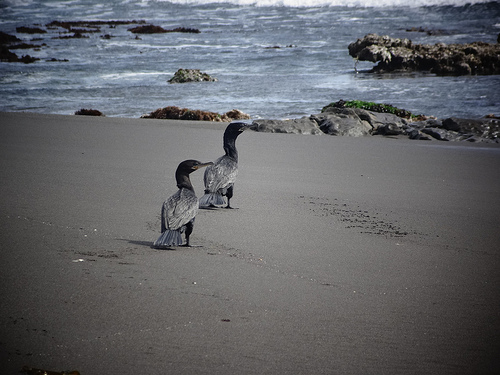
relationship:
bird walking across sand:
[150, 158, 217, 248] [302, 190, 394, 230]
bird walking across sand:
[194, 115, 253, 210] [302, 190, 394, 230]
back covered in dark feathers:
[150, 190, 201, 247] [160, 196, 195, 233]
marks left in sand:
[296, 192, 406, 239] [3, 111, 499, 373]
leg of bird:
[183, 223, 197, 247] [157, 150, 214, 255]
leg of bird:
[165, 228, 185, 245] [157, 150, 214, 255]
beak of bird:
[240, 123, 255, 132] [208, 115, 265, 225]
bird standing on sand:
[150, 158, 217, 248] [3, 111, 499, 373]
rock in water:
[248, 101, 495, 144] [2, 4, 499, 127]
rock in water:
[352, 33, 499, 73] [2, 4, 499, 127]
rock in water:
[168, 68, 217, 83] [2, 4, 499, 127]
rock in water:
[136, 105, 248, 117] [2, 4, 499, 127]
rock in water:
[0, 32, 47, 48] [2, 4, 499, 127]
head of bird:
[226, 118, 246, 139] [209, 119, 244, 210]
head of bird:
[174, 158, 211, 183] [149, 157, 216, 250]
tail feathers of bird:
[152, 228, 184, 253] [150, 148, 206, 258]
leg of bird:
[222, 187, 240, 208] [194, 115, 253, 210]